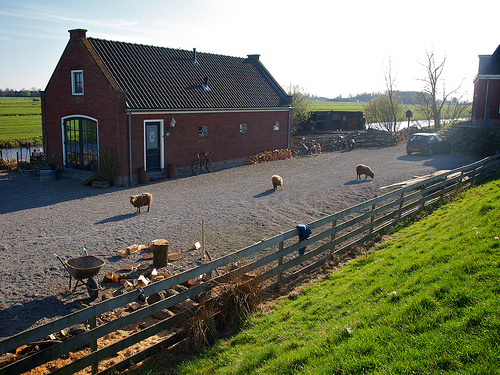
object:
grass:
[355, 352, 423, 374]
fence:
[0, 154, 499, 374]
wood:
[359, 195, 430, 214]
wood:
[94, 320, 134, 337]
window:
[71, 70, 85, 95]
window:
[198, 125, 208, 137]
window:
[240, 122, 248, 133]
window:
[273, 121, 279, 130]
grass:
[461, 353, 499, 374]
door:
[143, 119, 165, 175]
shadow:
[93, 213, 138, 225]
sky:
[2, 2, 493, 104]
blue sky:
[33, 1, 133, 16]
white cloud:
[394, 6, 457, 35]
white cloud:
[313, 34, 370, 67]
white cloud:
[245, 10, 299, 38]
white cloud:
[92, 18, 150, 33]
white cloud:
[218, 35, 255, 51]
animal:
[356, 164, 375, 179]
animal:
[271, 175, 283, 191]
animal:
[129, 193, 152, 213]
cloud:
[121, 3, 497, 108]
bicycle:
[191, 151, 215, 176]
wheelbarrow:
[53, 248, 106, 300]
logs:
[153, 239, 170, 267]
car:
[406, 132, 451, 156]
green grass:
[256, 316, 316, 343]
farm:
[10, 24, 499, 374]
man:
[32, 149, 38, 156]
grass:
[126, 349, 281, 374]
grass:
[0, 95, 473, 146]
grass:
[463, 190, 496, 230]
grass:
[1, 94, 39, 137]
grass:
[311, 97, 365, 110]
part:
[292, 318, 384, 371]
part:
[454, 221, 475, 240]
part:
[399, 238, 469, 276]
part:
[387, 297, 481, 352]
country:
[2, 88, 497, 370]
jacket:
[295, 223, 313, 256]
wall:
[166, 107, 291, 163]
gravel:
[186, 186, 267, 244]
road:
[8, 137, 452, 372]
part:
[233, 346, 297, 360]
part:
[265, 312, 321, 352]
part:
[345, 288, 402, 333]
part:
[386, 246, 418, 278]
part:
[424, 297, 470, 347]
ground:
[1, 97, 498, 373]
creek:
[2, 145, 46, 165]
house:
[38, 28, 292, 188]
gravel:
[2, 214, 57, 286]